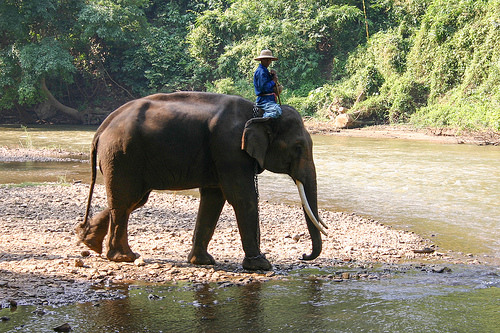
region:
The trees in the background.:
[1, 1, 494, 136]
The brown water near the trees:
[12, 116, 498, 326]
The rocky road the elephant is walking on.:
[1, 175, 436, 299]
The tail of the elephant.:
[81, 135, 96, 236]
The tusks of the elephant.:
[293, 180, 330, 232]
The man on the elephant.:
[251, 44, 285, 125]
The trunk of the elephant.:
[294, 172, 326, 260]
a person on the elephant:
[249, 45, 287, 116]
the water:
[227, 295, 306, 328]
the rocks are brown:
[345, 223, 401, 268]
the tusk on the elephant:
[298, 188, 328, 233]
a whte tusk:
[301, 208, 329, 235]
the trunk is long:
[307, 234, 329, 267]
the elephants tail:
[82, 178, 97, 224]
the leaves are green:
[368, 39, 446, 98]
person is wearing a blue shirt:
[253, 65, 276, 90]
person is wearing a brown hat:
[250, 50, 277, 60]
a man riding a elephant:
[73, 49, 333, 277]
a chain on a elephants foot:
[238, 100, 265, 275]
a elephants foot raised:
[75, 210, 108, 257]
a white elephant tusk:
[299, 173, 327, 240]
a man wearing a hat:
[253, 48, 275, 65]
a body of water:
[345, 137, 478, 227]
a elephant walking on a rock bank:
[31, 222, 431, 312]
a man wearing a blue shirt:
[250, 67, 277, 99]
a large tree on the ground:
[40, 66, 97, 125]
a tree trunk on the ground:
[331, 112, 365, 136]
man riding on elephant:
[250, 45, 283, 113]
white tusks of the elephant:
[287, 182, 332, 229]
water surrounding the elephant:
[2, 129, 499, 326]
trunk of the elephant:
[299, 187, 322, 259]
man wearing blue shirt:
[245, 49, 282, 115]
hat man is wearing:
[253, 46, 274, 61]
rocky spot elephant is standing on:
[0, 179, 411, 278]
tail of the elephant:
[78, 146, 99, 234]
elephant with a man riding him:
[84, 95, 323, 274]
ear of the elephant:
[239, 122, 275, 169]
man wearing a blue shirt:
[254, 65, 271, 94]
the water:
[290, 284, 356, 322]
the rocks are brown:
[345, 230, 391, 256]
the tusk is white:
[295, 189, 330, 235]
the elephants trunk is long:
[308, 235, 326, 260]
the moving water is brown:
[376, 159, 446, 214]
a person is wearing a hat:
[258, 45, 271, 57]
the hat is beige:
[258, 47, 274, 59]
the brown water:
[413, 177, 499, 246]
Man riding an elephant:
[74, 47, 333, 274]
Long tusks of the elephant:
[295, 176, 330, 234]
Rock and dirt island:
[0, 179, 428, 284]